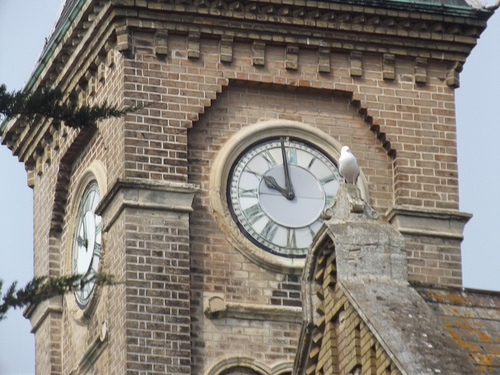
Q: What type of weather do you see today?
A: It is cloudy.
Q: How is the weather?
A: It is cloudy.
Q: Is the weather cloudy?
A: Yes, it is cloudy.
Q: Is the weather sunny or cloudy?
A: It is cloudy.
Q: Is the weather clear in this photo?
A: No, it is cloudy.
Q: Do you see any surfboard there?
A: No, there are no surfboards.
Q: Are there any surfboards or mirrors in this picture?
A: No, there are no surfboards or mirrors.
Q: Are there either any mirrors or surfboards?
A: No, there are no surfboards or mirrors.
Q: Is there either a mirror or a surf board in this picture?
A: No, there are no surfboards or mirrors.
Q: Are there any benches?
A: No, there are no benches.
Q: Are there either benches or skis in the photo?
A: No, there are no benches or skis.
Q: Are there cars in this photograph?
A: No, there are no cars.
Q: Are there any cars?
A: No, there are no cars.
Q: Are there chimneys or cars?
A: No, there are no cars or chimneys.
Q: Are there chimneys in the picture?
A: No, there are no chimneys.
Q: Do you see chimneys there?
A: No, there are no chimneys.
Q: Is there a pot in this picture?
A: No, there are no pots.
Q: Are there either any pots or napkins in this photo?
A: No, there are no pots or napkins.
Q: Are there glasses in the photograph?
A: No, there are no glasses.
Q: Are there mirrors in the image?
A: No, there are no mirrors.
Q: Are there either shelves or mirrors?
A: No, there are no mirrors or shelves.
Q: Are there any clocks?
A: Yes, there is a clock.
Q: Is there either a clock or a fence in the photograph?
A: Yes, there is a clock.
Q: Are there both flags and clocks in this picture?
A: No, there is a clock but no flags.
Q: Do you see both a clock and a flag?
A: No, there is a clock but no flags.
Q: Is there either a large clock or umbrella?
A: Yes, there is a large clock.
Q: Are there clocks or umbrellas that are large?
A: Yes, the clock is large.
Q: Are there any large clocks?
A: Yes, there is a large clock.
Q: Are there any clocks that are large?
A: Yes, there is a clock that is large.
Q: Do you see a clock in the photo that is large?
A: Yes, there is a clock that is large.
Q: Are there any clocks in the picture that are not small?
A: Yes, there is a large clock.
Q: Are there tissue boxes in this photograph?
A: No, there are no tissue boxes.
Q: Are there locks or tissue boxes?
A: No, there are no tissue boxes or locks.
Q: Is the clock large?
A: Yes, the clock is large.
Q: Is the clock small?
A: No, the clock is large.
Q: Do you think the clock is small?
A: No, the clock is large.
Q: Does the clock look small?
A: No, the clock is large.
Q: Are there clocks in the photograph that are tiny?
A: No, there is a clock but it is large.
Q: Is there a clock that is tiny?
A: No, there is a clock but it is large.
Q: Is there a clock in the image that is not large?
A: No, there is a clock but it is large.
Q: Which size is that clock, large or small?
A: The clock is large.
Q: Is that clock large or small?
A: The clock is large.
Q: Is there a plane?
A: No, there are no airplanes.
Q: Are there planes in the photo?
A: No, there are no planes.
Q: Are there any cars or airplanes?
A: No, there are no airplanes or cars.